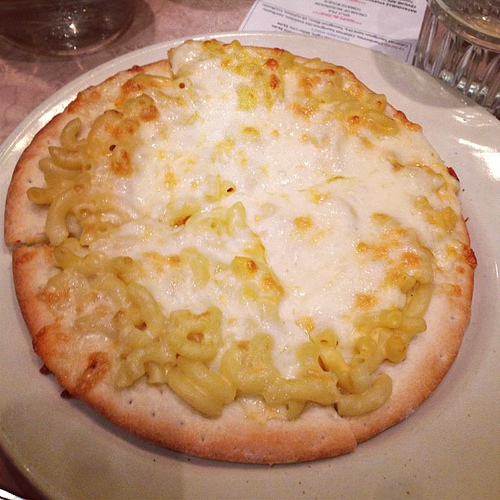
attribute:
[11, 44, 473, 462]
pizza — fully cooked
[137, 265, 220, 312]
cheese — melted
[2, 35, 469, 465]
macaroni — hardened, yellow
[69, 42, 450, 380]
cheese — melted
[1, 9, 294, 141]
tablecloth — pink, marbled